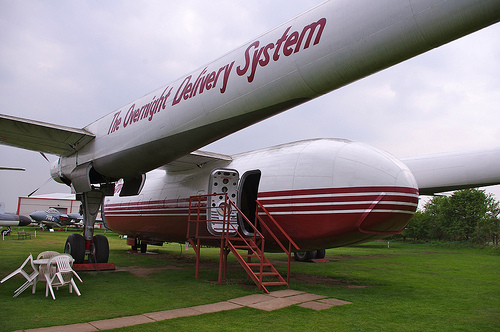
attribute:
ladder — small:
[208, 190, 312, 297]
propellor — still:
[1, 142, 88, 207]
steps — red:
[222, 199, 294, 293]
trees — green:
[406, 184, 498, 254]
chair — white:
[45, 252, 85, 301]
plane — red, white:
[1, 3, 498, 295]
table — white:
[11, 246, 108, 323]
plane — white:
[2, 3, 492, 265]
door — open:
[203, 166, 239, 237]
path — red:
[32, 241, 333, 330]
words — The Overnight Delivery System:
[103, 5, 334, 146]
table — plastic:
[35, 259, 62, 289]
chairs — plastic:
[0, 252, 40, 297]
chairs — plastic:
[47, 252, 80, 299]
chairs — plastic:
[35, 249, 65, 296]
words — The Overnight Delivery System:
[105, 17, 325, 136]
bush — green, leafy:
[418, 186, 498, 246]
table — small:
[27, 253, 77, 295]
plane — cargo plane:
[53, 143, 493, 285]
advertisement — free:
[105, 15, 328, 135]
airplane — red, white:
[3, 3, 497, 268]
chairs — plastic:
[8, 246, 84, 304]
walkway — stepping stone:
[140, 295, 321, 315]